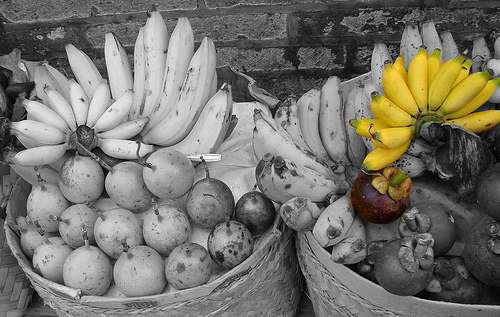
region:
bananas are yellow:
[388, 68, 460, 112]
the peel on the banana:
[376, 105, 411, 128]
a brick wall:
[253, 10, 312, 69]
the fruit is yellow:
[398, 72, 458, 107]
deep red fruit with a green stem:
[351, 165, 415, 221]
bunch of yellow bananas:
[347, 46, 499, 169]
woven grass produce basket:
[296, 228, 499, 314]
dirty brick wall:
[0, 0, 499, 176]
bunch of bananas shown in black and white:
[6, 75, 157, 167]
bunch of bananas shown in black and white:
[31, 10, 236, 165]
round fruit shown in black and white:
[114, 235, 166, 297]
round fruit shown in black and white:
[60, 235, 112, 293]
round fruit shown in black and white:
[231, 188, 274, 233]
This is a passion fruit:
[134, 140, 197, 197]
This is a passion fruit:
[233, 170, 284, 222]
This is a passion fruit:
[186, 160, 236, 224]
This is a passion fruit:
[142, 200, 204, 257]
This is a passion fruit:
[94, 148, 155, 212]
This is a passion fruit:
[72, 247, 123, 293]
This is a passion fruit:
[231, 185, 283, 228]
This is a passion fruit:
[23, 169, 62, 244]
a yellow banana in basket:
[385, 120, 419, 162]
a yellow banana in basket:
[354, 144, 396, 163]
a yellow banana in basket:
[340, 102, 395, 148]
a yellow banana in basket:
[382, 61, 429, 112]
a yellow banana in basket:
[407, 43, 447, 108]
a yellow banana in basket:
[422, 58, 469, 118]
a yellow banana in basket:
[462, 53, 476, 116]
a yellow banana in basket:
[423, 47, 457, 97]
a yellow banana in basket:
[434, 90, 496, 157]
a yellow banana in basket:
[462, 74, 494, 111]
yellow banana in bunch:
[360, 145, 411, 169]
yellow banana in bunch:
[368, 125, 413, 145]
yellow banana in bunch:
[347, 113, 383, 134]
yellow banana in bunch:
[370, 88, 410, 123]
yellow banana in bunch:
[381, 58, 418, 113]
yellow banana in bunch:
[406, 43, 428, 109]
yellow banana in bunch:
[425, 48, 442, 76]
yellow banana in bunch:
[431, 52, 463, 110]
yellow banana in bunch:
[441, 66, 488, 121]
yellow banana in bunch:
[448, 113, 495, 135]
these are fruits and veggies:
[62, 24, 416, 239]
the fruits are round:
[50, 173, 188, 247]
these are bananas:
[55, 107, 267, 245]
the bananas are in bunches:
[54, 78, 218, 113]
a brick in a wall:
[0, 0, 87, 20]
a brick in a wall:
[2, 22, 79, 52]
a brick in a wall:
[90, 12, 146, 53]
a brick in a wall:
[96, 0, 201, 17]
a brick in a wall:
[179, 13, 288, 45]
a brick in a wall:
[202, 0, 309, 10]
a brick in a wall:
[215, 43, 294, 71]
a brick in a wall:
[290, 44, 344, 72]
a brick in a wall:
[260, 69, 332, 101]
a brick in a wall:
[342, 39, 394, 67]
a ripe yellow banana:
[358, 137, 411, 169]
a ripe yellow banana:
[368, 128, 412, 149]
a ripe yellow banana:
[347, 116, 384, 136]